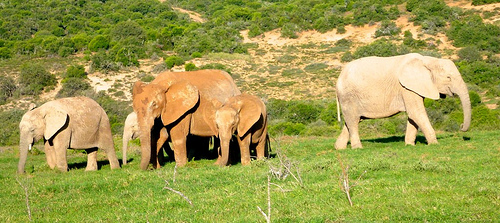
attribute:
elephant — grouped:
[13, 92, 117, 174]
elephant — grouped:
[118, 110, 140, 164]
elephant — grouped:
[111, 68, 239, 167]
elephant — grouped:
[205, 87, 273, 173]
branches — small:
[240, 122, 376, 214]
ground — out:
[80, 171, 449, 221]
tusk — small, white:
[15, 126, 35, 150]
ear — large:
[37, 102, 60, 154]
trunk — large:
[456, 81, 472, 132]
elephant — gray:
[15, 95, 121, 173]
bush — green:
[90, 50, 110, 74]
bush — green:
[114, 45, 142, 68]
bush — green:
[87, 32, 111, 52]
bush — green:
[109, 21, 148, 42]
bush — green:
[118, 33, 143, 48]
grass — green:
[1, 130, 484, 220]